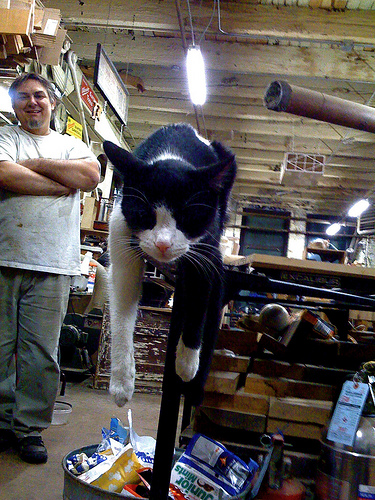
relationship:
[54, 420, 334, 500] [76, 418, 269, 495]
box of junior mints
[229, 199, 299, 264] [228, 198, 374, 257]
window in back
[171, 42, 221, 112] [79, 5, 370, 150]
florescent on ceiling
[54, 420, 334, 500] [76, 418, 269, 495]
garbage has trash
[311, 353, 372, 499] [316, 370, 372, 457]
fire hydrant has tag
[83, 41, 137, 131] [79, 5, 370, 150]
sign hangs from ceiling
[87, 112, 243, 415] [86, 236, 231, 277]
cat has whiskers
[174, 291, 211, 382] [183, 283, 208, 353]
foot edge black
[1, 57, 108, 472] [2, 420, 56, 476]
man has black shoe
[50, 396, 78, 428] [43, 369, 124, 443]
bowl on floor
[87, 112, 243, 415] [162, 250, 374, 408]
cat on edge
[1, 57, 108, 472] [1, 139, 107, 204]
man with crossing arms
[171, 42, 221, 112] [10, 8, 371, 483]
lights inside store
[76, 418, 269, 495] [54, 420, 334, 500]
bags in container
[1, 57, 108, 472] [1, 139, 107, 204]
man with arms crossed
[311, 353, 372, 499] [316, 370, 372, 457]
fire extinguisher with tag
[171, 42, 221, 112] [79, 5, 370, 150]
light in ceiling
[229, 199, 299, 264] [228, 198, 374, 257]
window on back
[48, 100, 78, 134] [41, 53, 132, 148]
clocks on wall